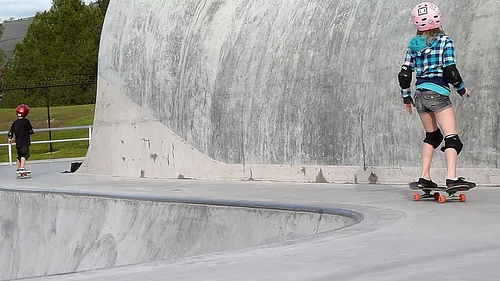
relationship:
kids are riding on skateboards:
[7, 2, 484, 205] [13, 169, 472, 204]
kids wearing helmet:
[394, 1, 484, 193] [408, 2, 444, 34]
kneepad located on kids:
[426, 124, 462, 157] [394, 1, 484, 193]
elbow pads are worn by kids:
[396, 67, 461, 88] [394, 1, 484, 193]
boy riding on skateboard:
[6, 101, 38, 181] [15, 168, 34, 183]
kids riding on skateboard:
[394, 1, 484, 193] [411, 180, 475, 214]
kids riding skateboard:
[394, 1, 484, 193] [411, 180, 475, 214]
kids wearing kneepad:
[394, 1, 484, 193] [426, 124, 462, 157]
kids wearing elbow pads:
[394, 1, 484, 193] [396, 67, 461, 88]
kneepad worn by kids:
[426, 124, 462, 157] [394, 1, 484, 193]